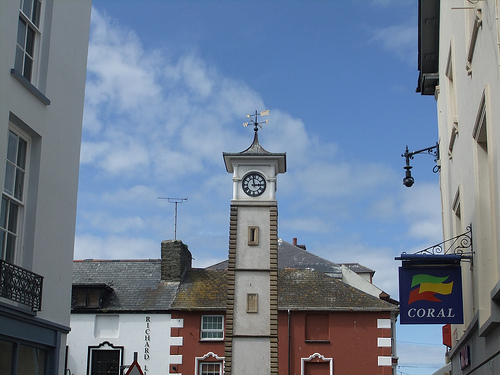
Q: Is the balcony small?
A: Yes, the balcony is small.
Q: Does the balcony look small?
A: Yes, the balcony is small.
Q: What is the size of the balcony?
A: The balcony is small.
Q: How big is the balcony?
A: The balcony is small.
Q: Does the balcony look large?
A: No, the balcony is small.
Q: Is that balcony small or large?
A: The balcony is small.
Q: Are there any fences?
A: No, there are no fences.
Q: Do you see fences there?
A: No, there are no fences.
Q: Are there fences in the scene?
A: No, there are no fences.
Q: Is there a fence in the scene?
A: No, there are no fences.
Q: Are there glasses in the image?
A: No, there are no glasses.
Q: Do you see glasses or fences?
A: No, there are no glasses or fences.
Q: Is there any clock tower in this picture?
A: Yes, there is a clock tower.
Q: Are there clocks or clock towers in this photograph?
A: Yes, there is a clock tower.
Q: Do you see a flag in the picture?
A: No, there are no flags.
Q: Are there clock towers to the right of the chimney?
A: Yes, there is a clock tower to the right of the chimney.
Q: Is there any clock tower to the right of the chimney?
A: Yes, there is a clock tower to the right of the chimney.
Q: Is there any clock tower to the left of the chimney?
A: No, the clock tower is to the right of the chimney.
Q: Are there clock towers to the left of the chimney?
A: No, the clock tower is to the right of the chimney.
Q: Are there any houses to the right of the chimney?
A: No, there is a clock tower to the right of the chimney.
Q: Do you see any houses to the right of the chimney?
A: No, there is a clock tower to the right of the chimney.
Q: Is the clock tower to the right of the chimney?
A: Yes, the clock tower is to the right of the chimney.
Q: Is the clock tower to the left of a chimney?
A: No, the clock tower is to the right of a chimney.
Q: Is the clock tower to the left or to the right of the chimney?
A: The clock tower is to the right of the chimney.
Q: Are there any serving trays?
A: No, there are no serving trays.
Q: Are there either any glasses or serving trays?
A: No, there are no serving trays or glasses.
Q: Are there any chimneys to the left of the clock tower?
A: Yes, there is a chimney to the left of the clock tower.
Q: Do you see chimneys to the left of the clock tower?
A: Yes, there is a chimney to the left of the clock tower.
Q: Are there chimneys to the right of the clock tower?
A: No, the chimney is to the left of the clock tower.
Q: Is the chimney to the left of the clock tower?
A: Yes, the chimney is to the left of the clock tower.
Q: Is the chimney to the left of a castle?
A: No, the chimney is to the left of the clock tower.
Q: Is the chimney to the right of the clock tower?
A: No, the chimney is to the left of the clock tower.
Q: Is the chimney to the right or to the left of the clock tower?
A: The chimney is to the left of the clock tower.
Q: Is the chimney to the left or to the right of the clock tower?
A: The chimney is to the left of the clock tower.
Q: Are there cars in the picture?
A: No, there are no cars.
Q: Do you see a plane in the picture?
A: No, there are no airplanes.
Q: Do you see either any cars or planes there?
A: No, there are no planes or cars.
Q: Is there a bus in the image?
A: No, there are no buses.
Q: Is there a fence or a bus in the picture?
A: No, there are no buses or fences.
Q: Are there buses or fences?
A: No, there are no buses or fences.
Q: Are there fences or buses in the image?
A: No, there are no buses or fences.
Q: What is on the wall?
A: The sign is on the wall.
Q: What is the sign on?
A: The sign is on the wall.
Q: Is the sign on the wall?
A: Yes, the sign is on the wall.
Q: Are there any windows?
A: Yes, there is a window.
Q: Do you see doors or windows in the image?
A: Yes, there is a window.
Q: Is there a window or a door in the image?
A: Yes, there is a window.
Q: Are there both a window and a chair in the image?
A: No, there is a window but no chairs.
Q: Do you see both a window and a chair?
A: No, there is a window but no chairs.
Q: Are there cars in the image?
A: No, there are no cars.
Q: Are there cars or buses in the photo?
A: No, there are no cars or buses.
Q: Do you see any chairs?
A: No, there are no chairs.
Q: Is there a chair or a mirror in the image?
A: No, there are no chairs or mirrors.